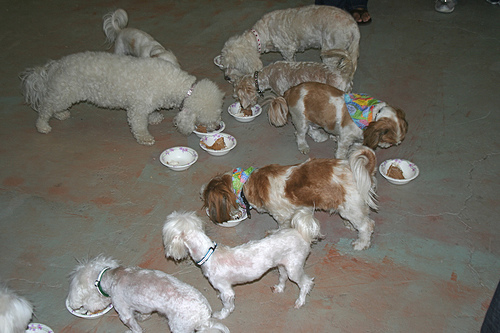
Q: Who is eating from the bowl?
A: Dogs.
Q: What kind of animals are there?
A: Dogs.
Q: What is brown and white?
A: The dogs.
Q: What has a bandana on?
A: The dog.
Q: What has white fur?
A: The dog.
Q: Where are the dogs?
A: On the ground.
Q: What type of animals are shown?
A: Dogs.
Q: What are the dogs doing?
A: Eating.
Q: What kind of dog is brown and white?
A: Cocker spaniel.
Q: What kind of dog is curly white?
A: Poodle.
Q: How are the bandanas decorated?
A: Colorfully.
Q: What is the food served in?
A: Bowls.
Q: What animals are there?
A: Dogs.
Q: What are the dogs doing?
A: Eating.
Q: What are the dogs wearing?
A: Collars.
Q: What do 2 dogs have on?
A: Bandanas.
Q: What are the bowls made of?
A: Glass.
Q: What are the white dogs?
A: Poodles.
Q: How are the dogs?
A: Leaning down.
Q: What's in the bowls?
A: Dog food.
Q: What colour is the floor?
A: Pink/white.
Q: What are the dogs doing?
A: Eating.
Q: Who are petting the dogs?
A: No one.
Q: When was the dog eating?
A: Now.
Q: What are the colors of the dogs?
A: White and brown.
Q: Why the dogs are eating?
A: They are eating.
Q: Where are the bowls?
A: On the ground.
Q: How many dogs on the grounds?
A: Nine.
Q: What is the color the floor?
A: Red and gray.